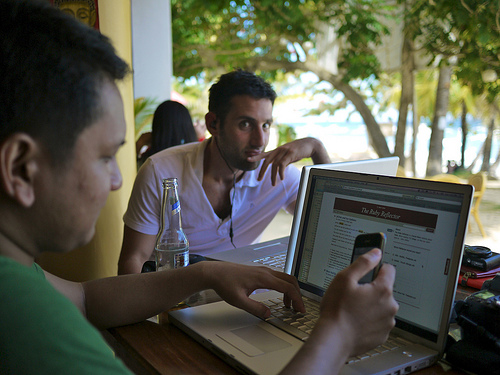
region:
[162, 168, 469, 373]
a silver laptop computer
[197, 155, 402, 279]
a silver laptop computer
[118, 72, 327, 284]
a man sitting at a table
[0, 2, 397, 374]
a man sitting at a table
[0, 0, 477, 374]
a man using a laptop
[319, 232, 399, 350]
cellphone in a man's hand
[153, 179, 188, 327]
a glass bottle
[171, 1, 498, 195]
a tree out of a window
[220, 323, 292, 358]
touchpad on a laptop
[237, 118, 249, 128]
a man's eye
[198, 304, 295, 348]
a laptop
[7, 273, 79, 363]
a green shirt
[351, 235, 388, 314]
man holding a cellphone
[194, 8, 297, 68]
the leaves on the tree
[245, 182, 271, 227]
man is wearing a white shirt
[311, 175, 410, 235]
the laptop screen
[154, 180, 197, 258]
a bottle on the table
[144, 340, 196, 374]
the brown table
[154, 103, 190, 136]
a person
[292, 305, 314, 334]
the keyboard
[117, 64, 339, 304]
This is a person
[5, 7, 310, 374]
This is a person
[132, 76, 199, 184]
This is a person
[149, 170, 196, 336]
This is a bottle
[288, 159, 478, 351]
This is a laptop screen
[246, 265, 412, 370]
This is a laptop keyboard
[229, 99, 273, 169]
Face of a person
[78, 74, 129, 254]
Face of a person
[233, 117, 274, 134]
Eyes of a person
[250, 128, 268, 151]
Nose of a person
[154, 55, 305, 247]
man wearing ear plugs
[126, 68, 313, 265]
man wears white shirt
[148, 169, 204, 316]
a bottle behind an arm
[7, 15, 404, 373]
man wears a green top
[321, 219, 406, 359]
hand holding a cell phone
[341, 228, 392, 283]
cell phone is black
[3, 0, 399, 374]
man holds a cell phone on right hand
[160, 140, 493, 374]
two laptops on a table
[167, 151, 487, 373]
laptops are color silver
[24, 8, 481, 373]
man is typing with left hand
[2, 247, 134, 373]
Man is wearing a green shirt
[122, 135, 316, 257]
Man is wearing a white shirt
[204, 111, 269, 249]
Man is wearing earphones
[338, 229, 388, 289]
Man is on cell phone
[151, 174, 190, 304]
Bottle is on the table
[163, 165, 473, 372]
Laptop is on the table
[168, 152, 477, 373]
Two laptops on the table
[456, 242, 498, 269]
Camera is on the table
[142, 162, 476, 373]
Man is typing on laptop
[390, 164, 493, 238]
Three yellow chairs